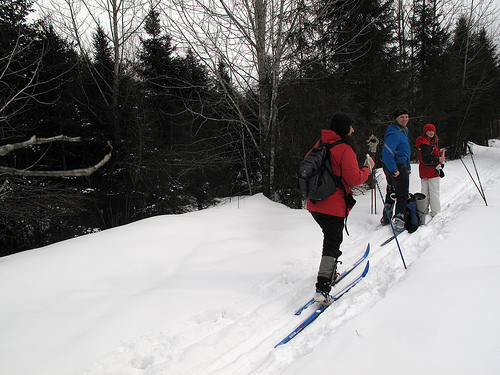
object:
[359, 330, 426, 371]
patch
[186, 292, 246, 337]
patch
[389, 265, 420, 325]
patch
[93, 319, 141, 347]
patch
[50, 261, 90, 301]
patch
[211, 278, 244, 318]
patch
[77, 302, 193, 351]
patch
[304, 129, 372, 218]
jacket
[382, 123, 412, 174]
jacket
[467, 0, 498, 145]
tree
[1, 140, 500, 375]
snow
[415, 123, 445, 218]
people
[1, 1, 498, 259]
trees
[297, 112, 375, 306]
woman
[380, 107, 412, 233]
man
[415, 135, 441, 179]
jacket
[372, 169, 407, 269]
ski pole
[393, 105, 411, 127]
hat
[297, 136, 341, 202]
backpack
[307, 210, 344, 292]
pants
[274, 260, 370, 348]
skis